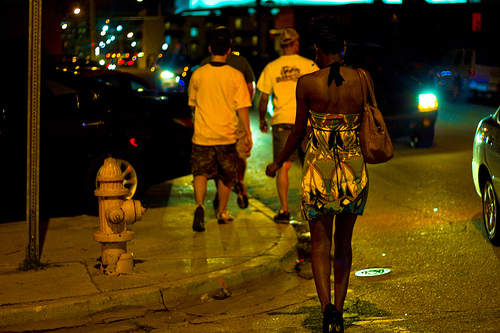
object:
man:
[255, 24, 325, 223]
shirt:
[256, 52, 323, 126]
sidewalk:
[2, 174, 295, 315]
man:
[186, 32, 254, 233]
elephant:
[299, 70, 385, 230]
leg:
[309, 196, 338, 331]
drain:
[352, 266, 392, 279]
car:
[472, 105, 499, 246]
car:
[265, 50, 439, 149]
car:
[149, 47, 258, 111]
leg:
[335, 208, 353, 316]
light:
[72, 7, 83, 19]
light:
[55, 17, 72, 32]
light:
[114, 21, 126, 31]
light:
[125, 30, 134, 40]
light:
[135, 47, 146, 58]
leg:
[274, 160, 292, 223]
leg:
[192, 157, 207, 233]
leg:
[214, 162, 234, 224]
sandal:
[192, 204, 204, 231]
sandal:
[215, 212, 235, 224]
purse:
[363, 106, 395, 165]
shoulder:
[346, 67, 372, 108]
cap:
[279, 28, 300, 46]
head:
[278, 28, 300, 54]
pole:
[27, 0, 46, 270]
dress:
[301, 106, 371, 222]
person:
[264, 36, 397, 331]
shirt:
[185, 61, 254, 146]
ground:
[432, 104, 481, 144]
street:
[270, 100, 500, 327]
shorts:
[189, 143, 247, 181]